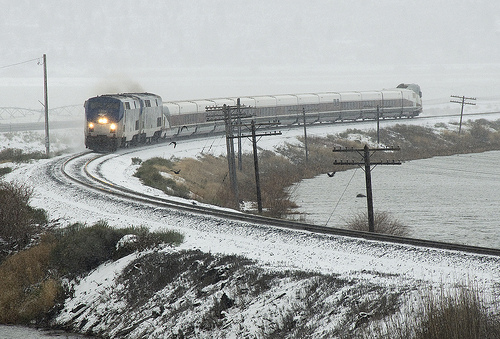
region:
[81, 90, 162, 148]
locomotive with its lights on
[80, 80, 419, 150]
locomotive hauling several car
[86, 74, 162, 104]
smoke coming out of locomotive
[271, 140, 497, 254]
large body of water by train tracks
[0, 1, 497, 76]
background is covered in snow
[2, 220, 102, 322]
thick bushes on side of traintracks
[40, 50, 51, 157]
wood utility pole on side of train track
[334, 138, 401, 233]
utility pole by train tracks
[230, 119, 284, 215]
utility pole by train tracks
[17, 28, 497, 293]
a train about to go around a bend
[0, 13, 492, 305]
a train about to go around a curve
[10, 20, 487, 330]
a train with its lights on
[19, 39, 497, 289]
a train in the fog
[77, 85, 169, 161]
the front car of a train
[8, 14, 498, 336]
a train on the tracks going around a curve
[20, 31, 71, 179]
a distant utility pole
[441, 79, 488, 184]
a utility pole that is leaning to the right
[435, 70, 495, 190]
a utility pole on a distant embankment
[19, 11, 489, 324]
A curve in the tracks with a train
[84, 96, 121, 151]
locomotive headlights are on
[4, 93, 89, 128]
irrigation equipment in a field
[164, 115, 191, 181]
three birds flying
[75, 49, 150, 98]
faint exhaust plume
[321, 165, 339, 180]
bird flying with wings up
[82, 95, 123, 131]
front of locomotive is blue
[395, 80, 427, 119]
caboose has a spoiler on top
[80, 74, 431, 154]
train chugging along tracks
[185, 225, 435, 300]
snow on the ground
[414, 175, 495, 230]
open water in the lake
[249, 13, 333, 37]
this is the sky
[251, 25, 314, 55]
the sky is blue in color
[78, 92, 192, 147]
this is a train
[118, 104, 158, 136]
the train is white in color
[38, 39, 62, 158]
this is a pole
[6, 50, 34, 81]
this is a electrical wire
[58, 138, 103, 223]
this is a railway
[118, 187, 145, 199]
this is a metal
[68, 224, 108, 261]
this is a grass area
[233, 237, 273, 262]
this is the snow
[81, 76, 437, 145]
a train going on the tracks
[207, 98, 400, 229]
power lines along the train tracks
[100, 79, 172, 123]
smoke coming from the train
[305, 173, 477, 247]
ground covered with snow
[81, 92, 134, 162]
the engine lights of the train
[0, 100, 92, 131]
sprinkler system in a farmer's field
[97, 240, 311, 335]
a snow covered hill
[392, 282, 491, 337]
tall brown weeds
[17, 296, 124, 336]
a body of water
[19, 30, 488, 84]
the cold gray winter sky